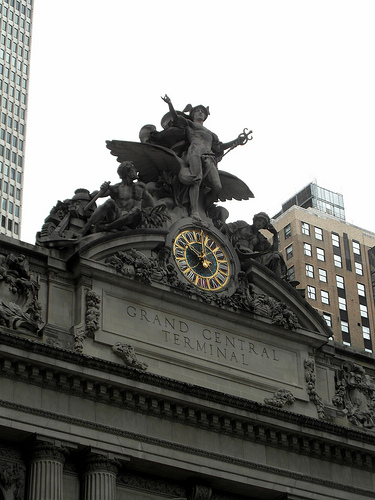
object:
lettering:
[125, 302, 136, 318]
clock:
[170, 223, 230, 295]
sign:
[88, 277, 329, 404]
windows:
[339, 324, 350, 334]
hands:
[159, 92, 171, 106]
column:
[84, 456, 118, 499]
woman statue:
[229, 209, 297, 290]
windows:
[353, 261, 364, 273]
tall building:
[270, 175, 346, 223]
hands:
[198, 224, 210, 258]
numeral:
[213, 248, 226, 262]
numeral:
[217, 261, 230, 274]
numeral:
[209, 277, 221, 292]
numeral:
[183, 268, 197, 283]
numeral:
[172, 242, 187, 258]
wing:
[102, 139, 185, 193]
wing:
[203, 169, 255, 203]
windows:
[362, 330, 370, 341]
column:
[30, 448, 69, 498]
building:
[0, 0, 35, 240]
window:
[303, 241, 313, 253]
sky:
[21, 0, 374, 248]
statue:
[103, 91, 255, 229]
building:
[0, 92, 374, 499]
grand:
[125, 304, 190, 336]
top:
[31, 94, 334, 341]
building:
[258, 202, 375, 356]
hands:
[180, 233, 209, 271]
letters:
[139, 306, 151, 326]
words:
[161, 325, 251, 366]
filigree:
[170, 227, 229, 293]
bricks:
[291, 261, 300, 273]